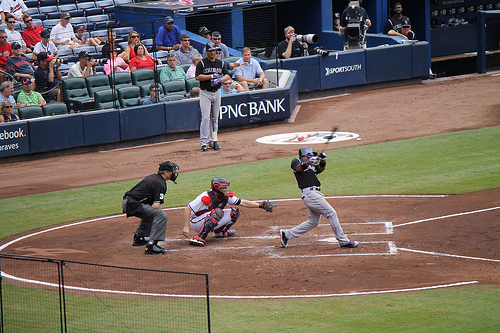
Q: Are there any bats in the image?
A: Yes, there is a bat.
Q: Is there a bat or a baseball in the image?
A: Yes, there is a bat.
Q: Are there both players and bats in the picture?
A: Yes, there are both a bat and a player.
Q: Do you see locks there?
A: No, there are no locks.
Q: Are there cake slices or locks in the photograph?
A: No, there are no locks or cake slices.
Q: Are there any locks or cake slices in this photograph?
A: No, there are no locks or cake slices.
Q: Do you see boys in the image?
A: No, there are no boys.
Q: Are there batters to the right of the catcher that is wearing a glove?
A: Yes, there is a batter to the right of the catcher.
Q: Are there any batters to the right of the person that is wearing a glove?
A: Yes, there is a batter to the right of the catcher.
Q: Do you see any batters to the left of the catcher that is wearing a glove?
A: No, the batter is to the right of the catcher.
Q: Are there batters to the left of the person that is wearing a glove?
A: No, the batter is to the right of the catcher.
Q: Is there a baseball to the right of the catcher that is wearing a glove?
A: No, there is a batter to the right of the catcher.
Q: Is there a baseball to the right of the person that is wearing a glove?
A: No, there is a batter to the right of the catcher.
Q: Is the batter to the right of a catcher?
A: Yes, the batter is to the right of a catcher.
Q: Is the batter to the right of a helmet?
A: No, the batter is to the right of a catcher.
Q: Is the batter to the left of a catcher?
A: No, the batter is to the right of a catcher.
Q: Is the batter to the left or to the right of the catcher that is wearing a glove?
A: The batter is to the right of the catcher.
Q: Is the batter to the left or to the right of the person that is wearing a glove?
A: The batter is to the right of the catcher.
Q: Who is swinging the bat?
A: The batter is swinging the bat.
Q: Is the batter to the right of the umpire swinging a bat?
A: Yes, the batter is swinging a bat.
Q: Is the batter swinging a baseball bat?
A: No, the batter is swinging a bat.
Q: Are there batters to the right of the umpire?
A: Yes, there is a batter to the right of the umpire.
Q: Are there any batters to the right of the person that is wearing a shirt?
A: Yes, there is a batter to the right of the umpire.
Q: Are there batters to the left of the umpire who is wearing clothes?
A: No, the batter is to the right of the umpire.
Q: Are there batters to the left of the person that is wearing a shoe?
A: No, the batter is to the right of the umpire.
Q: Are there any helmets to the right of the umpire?
A: No, there is a batter to the right of the umpire.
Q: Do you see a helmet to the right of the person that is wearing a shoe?
A: No, there is a batter to the right of the umpire.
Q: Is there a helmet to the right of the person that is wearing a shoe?
A: No, there is a batter to the right of the umpire.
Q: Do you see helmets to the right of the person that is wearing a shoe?
A: No, there is a batter to the right of the umpire.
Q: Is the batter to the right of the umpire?
A: Yes, the batter is to the right of the umpire.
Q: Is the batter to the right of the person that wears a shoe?
A: Yes, the batter is to the right of the umpire.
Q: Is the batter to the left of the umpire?
A: No, the batter is to the right of the umpire.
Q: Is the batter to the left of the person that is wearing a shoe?
A: No, the batter is to the right of the umpire.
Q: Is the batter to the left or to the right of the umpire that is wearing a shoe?
A: The batter is to the right of the umpire.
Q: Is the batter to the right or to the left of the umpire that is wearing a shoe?
A: The batter is to the right of the umpire.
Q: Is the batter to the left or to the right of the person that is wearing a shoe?
A: The batter is to the right of the umpire.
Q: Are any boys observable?
A: No, there are no boys.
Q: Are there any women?
A: Yes, there is a woman.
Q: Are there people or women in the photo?
A: Yes, there is a woman.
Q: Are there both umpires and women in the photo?
A: Yes, there are both a woman and an umpire.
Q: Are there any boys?
A: No, there are no boys.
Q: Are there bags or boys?
A: No, there are no boys or bags.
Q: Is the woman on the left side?
A: Yes, the woman is on the left of the image.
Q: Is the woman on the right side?
A: No, the woman is on the left of the image.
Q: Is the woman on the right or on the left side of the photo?
A: The woman is on the left of the image.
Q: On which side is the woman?
A: The woman is on the left of the image.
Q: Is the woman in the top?
A: Yes, the woman is in the top of the image.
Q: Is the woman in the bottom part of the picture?
A: No, the woman is in the top of the image.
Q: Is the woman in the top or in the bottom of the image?
A: The woman is in the top of the image.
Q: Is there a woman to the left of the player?
A: Yes, there is a woman to the left of the player.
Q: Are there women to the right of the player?
A: No, the woman is to the left of the player.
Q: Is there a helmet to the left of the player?
A: No, there is a woman to the left of the player.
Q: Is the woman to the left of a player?
A: Yes, the woman is to the left of a player.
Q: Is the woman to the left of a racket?
A: No, the woman is to the left of a player.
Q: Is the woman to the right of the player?
A: No, the woman is to the left of the player.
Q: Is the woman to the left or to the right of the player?
A: The woman is to the left of the player.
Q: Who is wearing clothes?
A: The umpire is wearing clothes.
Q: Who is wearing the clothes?
A: The umpire is wearing clothes.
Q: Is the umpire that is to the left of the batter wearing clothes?
A: Yes, the umpire is wearing clothes.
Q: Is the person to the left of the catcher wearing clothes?
A: Yes, the umpire is wearing clothes.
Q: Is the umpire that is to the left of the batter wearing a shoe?
A: Yes, the umpire is wearing a shoe.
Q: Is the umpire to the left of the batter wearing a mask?
A: No, the umpire is wearing a shoe.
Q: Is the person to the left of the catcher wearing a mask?
A: No, the umpire is wearing a shoe.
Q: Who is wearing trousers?
A: The umpire is wearing trousers.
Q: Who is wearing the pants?
A: The umpire is wearing trousers.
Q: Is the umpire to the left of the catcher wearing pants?
A: Yes, the umpire is wearing pants.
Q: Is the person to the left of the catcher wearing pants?
A: Yes, the umpire is wearing pants.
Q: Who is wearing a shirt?
A: The umpire is wearing a shirt.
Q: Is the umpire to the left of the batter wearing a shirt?
A: Yes, the umpire is wearing a shirt.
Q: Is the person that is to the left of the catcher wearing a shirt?
A: Yes, the umpire is wearing a shirt.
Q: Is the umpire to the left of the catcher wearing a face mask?
A: No, the umpire is wearing a shirt.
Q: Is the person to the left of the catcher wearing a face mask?
A: No, the umpire is wearing a shirt.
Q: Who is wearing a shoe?
A: The umpire is wearing a shoe.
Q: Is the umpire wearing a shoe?
A: Yes, the umpire is wearing a shoe.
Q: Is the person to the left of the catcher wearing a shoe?
A: Yes, the umpire is wearing a shoe.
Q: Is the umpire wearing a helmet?
A: No, the umpire is wearing a shoe.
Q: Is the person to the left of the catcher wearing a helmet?
A: No, the umpire is wearing a shoe.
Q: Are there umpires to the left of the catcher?
A: Yes, there is an umpire to the left of the catcher.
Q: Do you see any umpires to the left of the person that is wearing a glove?
A: Yes, there is an umpire to the left of the catcher.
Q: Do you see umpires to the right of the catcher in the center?
A: No, the umpire is to the left of the catcher.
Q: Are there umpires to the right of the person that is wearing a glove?
A: No, the umpire is to the left of the catcher.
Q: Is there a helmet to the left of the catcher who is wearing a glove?
A: No, there is an umpire to the left of the catcher.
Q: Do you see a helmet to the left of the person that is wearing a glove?
A: No, there is an umpire to the left of the catcher.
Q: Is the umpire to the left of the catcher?
A: Yes, the umpire is to the left of the catcher.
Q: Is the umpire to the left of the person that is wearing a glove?
A: Yes, the umpire is to the left of the catcher.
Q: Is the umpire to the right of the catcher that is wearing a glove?
A: No, the umpire is to the left of the catcher.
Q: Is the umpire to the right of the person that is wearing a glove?
A: No, the umpire is to the left of the catcher.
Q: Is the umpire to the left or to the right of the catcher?
A: The umpire is to the left of the catcher.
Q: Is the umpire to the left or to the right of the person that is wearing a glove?
A: The umpire is to the left of the catcher.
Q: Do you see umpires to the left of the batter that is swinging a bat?
A: Yes, there is an umpire to the left of the batter.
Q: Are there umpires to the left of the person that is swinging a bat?
A: Yes, there is an umpire to the left of the batter.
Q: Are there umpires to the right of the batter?
A: No, the umpire is to the left of the batter.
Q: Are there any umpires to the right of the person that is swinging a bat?
A: No, the umpire is to the left of the batter.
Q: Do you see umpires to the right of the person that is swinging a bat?
A: No, the umpire is to the left of the batter.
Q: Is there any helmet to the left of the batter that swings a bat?
A: No, there is an umpire to the left of the batter.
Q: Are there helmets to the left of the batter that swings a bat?
A: No, there is an umpire to the left of the batter.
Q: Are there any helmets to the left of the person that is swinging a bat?
A: No, there is an umpire to the left of the batter.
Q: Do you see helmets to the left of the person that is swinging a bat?
A: No, there is an umpire to the left of the batter.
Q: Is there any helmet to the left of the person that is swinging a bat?
A: No, there is an umpire to the left of the batter.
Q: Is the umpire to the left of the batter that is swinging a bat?
A: Yes, the umpire is to the left of the batter.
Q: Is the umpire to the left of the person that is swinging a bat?
A: Yes, the umpire is to the left of the batter.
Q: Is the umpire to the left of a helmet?
A: No, the umpire is to the left of the batter.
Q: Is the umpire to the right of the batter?
A: No, the umpire is to the left of the batter.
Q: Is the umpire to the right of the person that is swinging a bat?
A: No, the umpire is to the left of the batter.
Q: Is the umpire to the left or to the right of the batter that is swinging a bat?
A: The umpire is to the left of the batter.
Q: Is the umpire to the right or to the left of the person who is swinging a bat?
A: The umpire is to the left of the batter.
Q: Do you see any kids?
A: No, there are no kids.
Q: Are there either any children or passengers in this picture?
A: No, there are no children or passengers.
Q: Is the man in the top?
A: Yes, the man is in the top of the image.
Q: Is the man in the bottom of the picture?
A: No, the man is in the top of the image.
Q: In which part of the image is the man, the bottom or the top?
A: The man is in the top of the image.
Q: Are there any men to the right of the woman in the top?
A: Yes, there is a man to the right of the woman.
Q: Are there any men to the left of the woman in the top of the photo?
A: No, the man is to the right of the woman.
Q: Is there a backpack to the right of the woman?
A: No, there is a man to the right of the woman.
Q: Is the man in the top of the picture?
A: Yes, the man is in the top of the image.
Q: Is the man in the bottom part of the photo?
A: No, the man is in the top of the image.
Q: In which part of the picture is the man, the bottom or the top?
A: The man is in the top of the image.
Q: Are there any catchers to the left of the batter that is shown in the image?
A: Yes, there is a catcher to the left of the batter.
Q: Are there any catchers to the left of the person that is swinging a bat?
A: Yes, there is a catcher to the left of the batter.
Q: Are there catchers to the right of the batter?
A: No, the catcher is to the left of the batter.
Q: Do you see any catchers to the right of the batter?
A: No, the catcher is to the left of the batter.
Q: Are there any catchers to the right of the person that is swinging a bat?
A: No, the catcher is to the left of the batter.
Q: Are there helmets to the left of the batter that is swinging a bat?
A: No, there is a catcher to the left of the batter.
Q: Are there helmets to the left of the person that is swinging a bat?
A: No, there is a catcher to the left of the batter.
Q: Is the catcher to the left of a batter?
A: Yes, the catcher is to the left of a batter.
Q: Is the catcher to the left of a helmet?
A: No, the catcher is to the left of a batter.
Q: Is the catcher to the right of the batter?
A: No, the catcher is to the left of the batter.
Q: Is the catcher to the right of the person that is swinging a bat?
A: No, the catcher is to the left of the batter.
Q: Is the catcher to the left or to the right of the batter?
A: The catcher is to the left of the batter.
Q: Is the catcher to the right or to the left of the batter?
A: The catcher is to the left of the batter.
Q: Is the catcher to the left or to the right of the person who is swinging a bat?
A: The catcher is to the left of the batter.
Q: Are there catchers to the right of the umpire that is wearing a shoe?
A: Yes, there is a catcher to the right of the umpire.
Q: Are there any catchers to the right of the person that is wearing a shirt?
A: Yes, there is a catcher to the right of the umpire.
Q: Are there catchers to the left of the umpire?
A: No, the catcher is to the right of the umpire.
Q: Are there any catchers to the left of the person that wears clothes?
A: No, the catcher is to the right of the umpire.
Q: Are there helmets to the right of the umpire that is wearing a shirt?
A: No, there is a catcher to the right of the umpire.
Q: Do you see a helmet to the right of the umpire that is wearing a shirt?
A: No, there is a catcher to the right of the umpire.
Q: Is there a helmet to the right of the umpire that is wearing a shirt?
A: No, there is a catcher to the right of the umpire.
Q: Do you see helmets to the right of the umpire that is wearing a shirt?
A: No, there is a catcher to the right of the umpire.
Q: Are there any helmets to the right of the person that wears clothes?
A: No, there is a catcher to the right of the umpire.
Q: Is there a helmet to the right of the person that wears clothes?
A: No, there is a catcher to the right of the umpire.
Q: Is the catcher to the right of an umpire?
A: Yes, the catcher is to the right of an umpire.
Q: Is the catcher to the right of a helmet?
A: No, the catcher is to the right of an umpire.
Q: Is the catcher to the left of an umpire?
A: No, the catcher is to the right of an umpire.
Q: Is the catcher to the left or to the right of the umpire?
A: The catcher is to the right of the umpire.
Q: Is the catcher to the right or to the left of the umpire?
A: The catcher is to the right of the umpire.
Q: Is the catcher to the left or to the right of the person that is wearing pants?
A: The catcher is to the right of the umpire.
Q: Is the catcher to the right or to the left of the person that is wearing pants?
A: The catcher is to the right of the umpire.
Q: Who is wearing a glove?
A: The catcher is wearing a glove.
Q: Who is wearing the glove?
A: The catcher is wearing a glove.